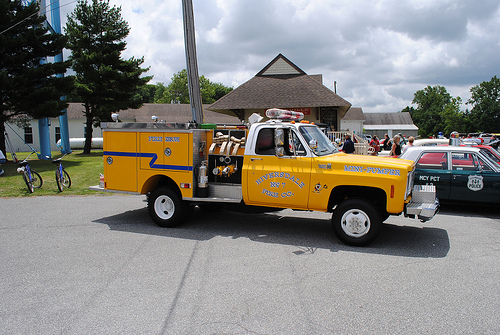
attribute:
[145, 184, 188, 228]
tire — black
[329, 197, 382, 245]
tire — black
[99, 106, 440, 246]
truck — yellow, bright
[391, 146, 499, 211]
car — green, vintage, white, parked, old fashion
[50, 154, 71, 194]
bicycle — blue, parked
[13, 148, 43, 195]
bicycle — blue, parked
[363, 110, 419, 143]
building — background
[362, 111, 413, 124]
roof — brown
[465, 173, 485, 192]
police logo — white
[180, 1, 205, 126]
ladder — vertical, grey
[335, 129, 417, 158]
people — wandering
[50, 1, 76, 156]
pole — tall, blue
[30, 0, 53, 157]
pole — tall, blue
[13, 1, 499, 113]
sky — grey, overcast, cloudy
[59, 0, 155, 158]
tree — green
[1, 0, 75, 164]
tree — green